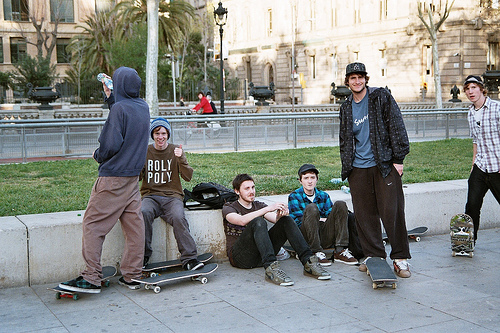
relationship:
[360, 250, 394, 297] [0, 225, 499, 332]
skateboard on ground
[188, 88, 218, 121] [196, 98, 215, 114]
person wearing shirt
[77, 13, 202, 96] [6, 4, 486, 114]
trees in background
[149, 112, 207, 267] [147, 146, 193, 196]
boy wearing shirt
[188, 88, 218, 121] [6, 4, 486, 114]
person in background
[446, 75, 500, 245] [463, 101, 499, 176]
boy wearing shirt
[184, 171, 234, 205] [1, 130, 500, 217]
backpack on ground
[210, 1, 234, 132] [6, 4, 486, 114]
lamp post in background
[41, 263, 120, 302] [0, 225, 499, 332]
skateboard on ground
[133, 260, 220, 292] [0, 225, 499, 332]
skateboard on ground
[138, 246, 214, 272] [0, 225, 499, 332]
skateboard on ground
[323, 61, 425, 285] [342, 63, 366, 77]
boy in hat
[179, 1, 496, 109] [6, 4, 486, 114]
building in background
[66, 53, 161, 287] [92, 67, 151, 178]
person in hoodie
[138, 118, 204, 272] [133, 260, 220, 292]
boy and skateboard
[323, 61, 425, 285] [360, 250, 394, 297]
person and skateboard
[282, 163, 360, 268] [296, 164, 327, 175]
man in cap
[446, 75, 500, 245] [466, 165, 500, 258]
man in pants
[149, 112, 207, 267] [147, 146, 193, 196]
man in shirt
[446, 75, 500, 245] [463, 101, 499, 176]
man in shirt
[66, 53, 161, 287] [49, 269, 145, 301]
man wearing sneakers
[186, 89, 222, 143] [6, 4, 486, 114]
bike rider in background